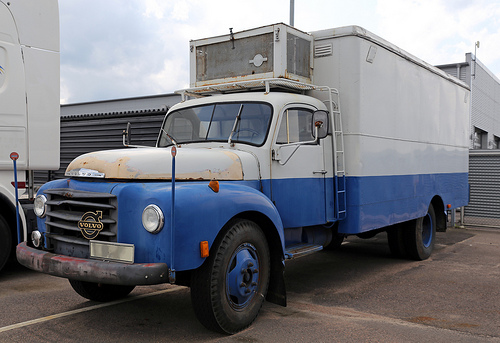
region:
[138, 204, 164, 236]
a light on a truck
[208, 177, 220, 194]
a light on a truck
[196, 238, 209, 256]
a light on a truck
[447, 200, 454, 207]
a light on a truck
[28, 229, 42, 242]
a light on a truck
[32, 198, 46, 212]
a light on a truck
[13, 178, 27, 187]
a light on a truck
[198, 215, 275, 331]
a tire on a truck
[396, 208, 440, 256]
a tire on a truck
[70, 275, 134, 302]
a tire on a truck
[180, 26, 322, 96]
refrigeration system for transporting food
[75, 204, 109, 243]
round emblem with volvo on it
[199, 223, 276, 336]
black wheel with blue in the middle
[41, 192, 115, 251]
grid with emblem on it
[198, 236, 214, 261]
small rectangle orange reflector light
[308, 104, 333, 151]
rear view mirror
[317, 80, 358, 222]
ladder with seven rungs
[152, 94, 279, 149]
pair of windows with wipers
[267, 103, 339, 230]
door painted blue and white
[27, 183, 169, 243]
two headlights on truck front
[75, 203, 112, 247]
logo of trucker maker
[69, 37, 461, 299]
old blue and gray truck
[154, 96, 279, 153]
windshield on truck front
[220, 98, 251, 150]
windshield wiper on truck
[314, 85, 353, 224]
ladder on side of truck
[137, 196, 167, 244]
headlight on front of truck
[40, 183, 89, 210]
bent grill on truck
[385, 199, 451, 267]
rear tire on truck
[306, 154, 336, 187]
handle on truck door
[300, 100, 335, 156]
side view mirror on truck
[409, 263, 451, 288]
part of a road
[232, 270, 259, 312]
part of a rim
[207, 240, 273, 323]
part of a wheel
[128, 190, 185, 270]
part of a headlight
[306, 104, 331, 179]
part of a side mirror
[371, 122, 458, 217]
side of a truck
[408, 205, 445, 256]
part of the back wheel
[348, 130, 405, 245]
part of a truck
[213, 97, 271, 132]
part of a window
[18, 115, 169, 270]
front of a lorry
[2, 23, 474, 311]
a old blue and white truck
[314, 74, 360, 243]
a ladder on a truck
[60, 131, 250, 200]
a hood of a truck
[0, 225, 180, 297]
a black bumper on a truck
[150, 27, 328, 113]
a refrigeration unit on top of a truck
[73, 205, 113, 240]
a company logo on a truck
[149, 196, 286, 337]
the front wheels of a truck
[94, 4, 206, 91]
white clouds in the sky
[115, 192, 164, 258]
a headlight on a truck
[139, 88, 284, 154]
windshield wipers on a truck